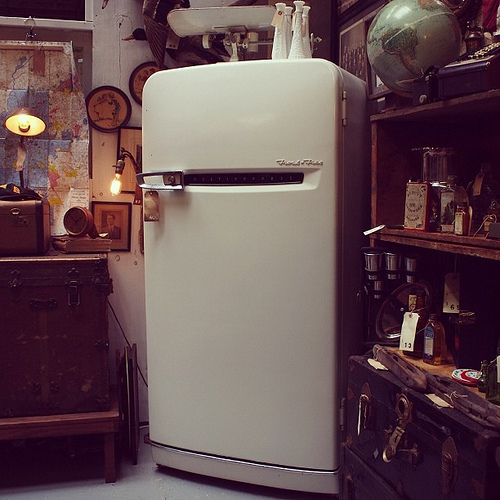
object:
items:
[403, 146, 499, 241]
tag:
[399, 312, 420, 352]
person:
[286, 119, 428, 203]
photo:
[339, 19, 371, 95]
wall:
[96, 138, 113, 174]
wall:
[96, 0, 122, 60]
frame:
[85, 85, 132, 133]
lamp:
[109, 159, 125, 197]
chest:
[0, 198, 52, 257]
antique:
[423, 314, 448, 367]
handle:
[135, 169, 185, 190]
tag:
[144, 190, 160, 220]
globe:
[366, 1, 463, 99]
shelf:
[367, 86, 500, 400]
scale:
[166, 0, 277, 63]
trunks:
[0, 252, 115, 419]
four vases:
[271, 0, 313, 60]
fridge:
[135, 57, 370, 495]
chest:
[339, 355, 500, 500]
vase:
[271, 3, 288, 60]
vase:
[285, 7, 292, 60]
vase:
[287, 1, 308, 59]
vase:
[302, 5, 313, 58]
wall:
[119, 266, 143, 331]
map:
[0, 40, 90, 236]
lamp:
[0, 107, 46, 201]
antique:
[373, 344, 428, 393]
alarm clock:
[63, 205, 93, 236]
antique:
[404, 179, 431, 233]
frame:
[91, 201, 132, 253]